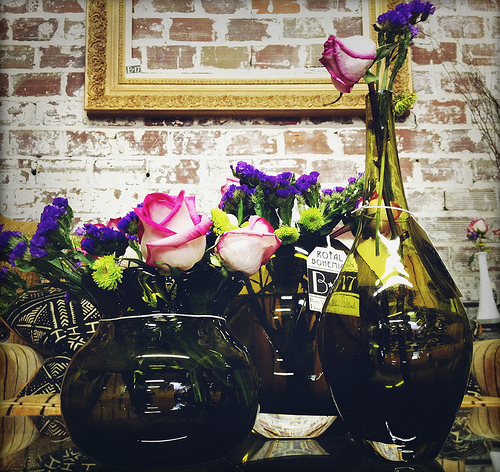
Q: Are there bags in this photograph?
A: No, there are no bags.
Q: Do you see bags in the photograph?
A: No, there are no bags.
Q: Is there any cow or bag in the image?
A: No, there are no bags or cows.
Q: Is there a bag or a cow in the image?
A: No, there are no bags or cows.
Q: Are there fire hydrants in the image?
A: No, there are no fire hydrants.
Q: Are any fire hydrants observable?
A: No, there are no fire hydrants.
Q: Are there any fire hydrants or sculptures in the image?
A: No, there are no fire hydrants or sculptures.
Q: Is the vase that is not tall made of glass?
A: Yes, the vase is made of glass.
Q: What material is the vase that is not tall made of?
A: The vase is made of glass.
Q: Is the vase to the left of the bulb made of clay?
A: No, the vase is made of glass.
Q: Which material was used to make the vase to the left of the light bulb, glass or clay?
A: The vase is made of glass.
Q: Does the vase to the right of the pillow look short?
A: Yes, the vase is short.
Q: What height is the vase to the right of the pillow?
A: The vase is short.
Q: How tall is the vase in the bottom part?
A: The vase is short.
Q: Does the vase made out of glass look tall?
A: No, the vase is short.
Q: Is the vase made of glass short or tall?
A: The vase is short.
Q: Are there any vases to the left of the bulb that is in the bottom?
A: Yes, there is a vase to the left of the bulb.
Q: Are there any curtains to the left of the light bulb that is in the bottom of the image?
A: No, there is a vase to the left of the bulb.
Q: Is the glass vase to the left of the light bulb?
A: Yes, the vase is to the left of the light bulb.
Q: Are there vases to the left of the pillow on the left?
A: No, the vase is to the right of the pillow.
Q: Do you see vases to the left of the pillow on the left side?
A: No, the vase is to the right of the pillow.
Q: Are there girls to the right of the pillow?
A: No, there is a vase to the right of the pillow.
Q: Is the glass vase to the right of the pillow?
A: Yes, the vase is to the right of the pillow.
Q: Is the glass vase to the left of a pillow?
A: No, the vase is to the right of a pillow.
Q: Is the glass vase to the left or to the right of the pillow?
A: The vase is to the right of the pillow.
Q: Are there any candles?
A: No, there are no candles.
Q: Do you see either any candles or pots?
A: No, there are no candles or pots.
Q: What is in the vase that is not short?
A: The flowers are in the vase.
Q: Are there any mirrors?
A: No, there are no mirrors.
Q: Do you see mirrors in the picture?
A: No, there are no mirrors.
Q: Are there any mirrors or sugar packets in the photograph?
A: No, there are no mirrors or sugar packets.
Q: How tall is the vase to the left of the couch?
A: The vase is tall.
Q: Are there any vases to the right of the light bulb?
A: Yes, there is a vase to the right of the light bulb.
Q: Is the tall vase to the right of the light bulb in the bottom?
A: Yes, the vase is to the right of the bulb.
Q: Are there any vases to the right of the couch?
A: No, the vase is to the left of the couch.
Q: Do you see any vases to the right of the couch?
A: No, the vase is to the left of the couch.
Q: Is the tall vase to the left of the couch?
A: Yes, the vase is to the left of the couch.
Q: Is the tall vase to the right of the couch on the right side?
A: No, the vase is to the left of the couch.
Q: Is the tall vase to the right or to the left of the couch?
A: The vase is to the left of the couch.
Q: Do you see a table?
A: Yes, there is a table.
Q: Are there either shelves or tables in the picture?
A: Yes, there is a table.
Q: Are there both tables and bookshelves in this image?
A: No, there is a table but no bookshelves.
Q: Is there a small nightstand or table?
A: Yes, there is a small table.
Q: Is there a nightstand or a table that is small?
A: Yes, the table is small.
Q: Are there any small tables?
A: Yes, there is a small table.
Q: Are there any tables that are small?
A: Yes, there is a table that is small.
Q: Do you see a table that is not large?
A: Yes, there is a small table.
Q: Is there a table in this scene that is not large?
A: Yes, there is a small table.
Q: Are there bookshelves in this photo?
A: No, there are no bookshelves.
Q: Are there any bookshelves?
A: No, there are no bookshelves.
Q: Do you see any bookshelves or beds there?
A: No, there are no bookshelves or beds.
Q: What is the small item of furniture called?
A: The piece of furniture is a table.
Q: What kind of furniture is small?
A: The furniture is a table.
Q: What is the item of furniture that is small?
A: The piece of furniture is a table.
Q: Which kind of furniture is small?
A: The furniture is a table.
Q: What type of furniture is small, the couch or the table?
A: The table is small.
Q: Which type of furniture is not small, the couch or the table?
A: The couch is not small.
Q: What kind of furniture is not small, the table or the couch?
A: The couch is not small.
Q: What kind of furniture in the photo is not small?
A: The furniture is a couch.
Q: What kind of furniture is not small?
A: The furniture is a couch.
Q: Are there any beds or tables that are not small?
A: No, there is a table but it is small.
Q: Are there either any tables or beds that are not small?
A: No, there is a table but it is small.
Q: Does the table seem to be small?
A: Yes, the table is small.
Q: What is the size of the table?
A: The table is small.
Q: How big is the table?
A: The table is small.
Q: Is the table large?
A: No, the table is small.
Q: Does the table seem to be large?
A: No, the table is small.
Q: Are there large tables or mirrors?
A: No, there is a table but it is small.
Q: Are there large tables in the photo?
A: No, there is a table but it is small.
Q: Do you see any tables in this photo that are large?
A: No, there is a table but it is small.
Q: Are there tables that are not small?
A: No, there is a table but it is small.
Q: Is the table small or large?
A: The table is small.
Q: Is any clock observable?
A: No, there are no clocks.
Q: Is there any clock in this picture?
A: No, there are no clocks.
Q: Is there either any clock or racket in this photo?
A: No, there are no clocks or rackets.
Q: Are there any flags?
A: No, there are no flags.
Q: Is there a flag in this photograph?
A: No, there are no flags.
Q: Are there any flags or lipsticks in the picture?
A: No, there are no flags or lipsticks.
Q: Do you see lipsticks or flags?
A: No, there are no flags or lipsticks.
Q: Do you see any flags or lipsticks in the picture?
A: No, there are no flags or lipsticks.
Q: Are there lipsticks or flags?
A: No, there are no flags or lipsticks.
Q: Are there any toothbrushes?
A: No, there are no toothbrushes.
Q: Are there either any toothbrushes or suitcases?
A: No, there are no toothbrushes or suitcases.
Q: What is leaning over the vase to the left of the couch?
A: The rose is leaning over the vase.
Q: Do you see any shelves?
A: No, there are no shelves.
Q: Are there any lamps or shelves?
A: No, there are no shelves or lamps.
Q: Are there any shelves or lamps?
A: No, there are no shelves or lamps.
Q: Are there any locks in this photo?
A: No, there are no locks.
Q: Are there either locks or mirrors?
A: No, there are no locks or mirrors.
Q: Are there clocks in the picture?
A: No, there are no clocks.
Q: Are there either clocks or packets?
A: No, there are no clocks or packets.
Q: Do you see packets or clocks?
A: No, there are no clocks or packets.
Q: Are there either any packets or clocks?
A: No, there are no clocks or packets.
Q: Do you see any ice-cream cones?
A: No, there are no ice-cream cones.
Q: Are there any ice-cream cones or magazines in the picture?
A: No, there are no ice-cream cones or magazines.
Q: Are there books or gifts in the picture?
A: No, there are no books or gifts.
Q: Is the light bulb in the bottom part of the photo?
A: Yes, the light bulb is in the bottom of the image.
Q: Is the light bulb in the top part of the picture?
A: No, the light bulb is in the bottom of the image.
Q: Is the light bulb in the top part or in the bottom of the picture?
A: The light bulb is in the bottom of the image.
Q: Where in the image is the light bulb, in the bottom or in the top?
A: The light bulb is in the bottom of the image.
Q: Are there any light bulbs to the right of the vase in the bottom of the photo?
A: Yes, there is a light bulb to the right of the vase.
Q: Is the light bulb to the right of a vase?
A: Yes, the light bulb is to the right of a vase.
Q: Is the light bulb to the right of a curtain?
A: No, the light bulb is to the right of a vase.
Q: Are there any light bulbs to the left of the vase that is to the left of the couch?
A: Yes, there is a light bulb to the left of the vase.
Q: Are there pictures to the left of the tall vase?
A: No, there is a light bulb to the left of the vase.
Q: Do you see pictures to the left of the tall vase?
A: No, there is a light bulb to the left of the vase.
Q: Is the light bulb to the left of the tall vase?
A: Yes, the light bulb is to the left of the vase.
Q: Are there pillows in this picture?
A: Yes, there is a pillow.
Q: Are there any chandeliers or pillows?
A: Yes, there is a pillow.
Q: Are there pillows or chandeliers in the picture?
A: Yes, there is a pillow.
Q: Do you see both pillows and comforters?
A: No, there is a pillow but no comforters.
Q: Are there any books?
A: No, there are no books.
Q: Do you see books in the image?
A: No, there are no books.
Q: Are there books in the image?
A: No, there are no books.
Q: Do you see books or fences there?
A: No, there are no books or fences.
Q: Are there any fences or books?
A: No, there are no books or fences.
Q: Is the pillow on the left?
A: Yes, the pillow is on the left of the image.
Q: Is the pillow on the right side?
A: No, the pillow is on the left of the image.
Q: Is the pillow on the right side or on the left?
A: The pillow is on the left of the image.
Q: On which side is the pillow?
A: The pillow is on the left of the image.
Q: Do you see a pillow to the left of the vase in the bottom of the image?
A: Yes, there is a pillow to the left of the vase.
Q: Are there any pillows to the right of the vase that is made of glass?
A: No, the pillow is to the left of the vase.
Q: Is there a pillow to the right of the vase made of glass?
A: No, the pillow is to the left of the vase.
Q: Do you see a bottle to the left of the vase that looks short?
A: No, there is a pillow to the left of the vase.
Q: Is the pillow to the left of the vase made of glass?
A: Yes, the pillow is to the left of the vase.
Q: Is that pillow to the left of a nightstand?
A: No, the pillow is to the left of the vase.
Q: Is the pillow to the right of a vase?
A: No, the pillow is to the left of a vase.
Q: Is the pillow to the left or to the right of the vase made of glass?
A: The pillow is to the left of the vase.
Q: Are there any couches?
A: Yes, there is a couch.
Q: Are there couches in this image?
A: Yes, there is a couch.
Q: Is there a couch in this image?
A: Yes, there is a couch.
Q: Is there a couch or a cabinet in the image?
A: Yes, there is a couch.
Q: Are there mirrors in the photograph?
A: No, there are no mirrors.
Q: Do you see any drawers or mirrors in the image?
A: No, there are no mirrors or drawers.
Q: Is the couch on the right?
A: Yes, the couch is on the right of the image.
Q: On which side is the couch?
A: The couch is on the right of the image.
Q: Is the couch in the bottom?
A: Yes, the couch is in the bottom of the image.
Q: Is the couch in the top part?
A: No, the couch is in the bottom of the image.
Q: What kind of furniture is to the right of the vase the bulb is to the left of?
A: The piece of furniture is a couch.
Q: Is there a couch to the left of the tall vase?
A: No, the couch is to the right of the vase.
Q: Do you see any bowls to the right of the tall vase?
A: No, there is a couch to the right of the vase.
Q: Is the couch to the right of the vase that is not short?
A: Yes, the couch is to the right of the vase.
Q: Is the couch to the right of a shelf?
A: No, the couch is to the right of the vase.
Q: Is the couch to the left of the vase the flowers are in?
A: No, the couch is to the right of the vase.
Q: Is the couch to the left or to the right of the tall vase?
A: The couch is to the right of the vase.